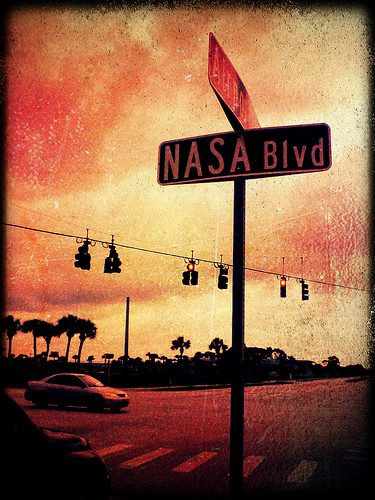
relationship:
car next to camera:
[21, 354, 137, 414] [26, 411, 102, 461]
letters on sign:
[160, 144, 180, 180] [158, 122, 333, 185]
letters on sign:
[183, 138, 202, 176] [158, 122, 333, 185]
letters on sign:
[205, 136, 223, 174] [158, 122, 333, 185]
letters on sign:
[228, 135, 252, 173] [158, 122, 333, 185]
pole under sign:
[226, 174, 245, 498] [152, 33, 337, 187]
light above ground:
[278, 276, 287, 296] [6, 378, 371, 497]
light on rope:
[272, 264, 289, 309] [289, 262, 358, 304]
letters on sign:
[164, 144, 180, 180] [158, 122, 333, 185]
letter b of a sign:
[261, 138, 278, 171] [157, 118, 335, 179]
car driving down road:
[24, 373, 130, 414] [13, 378, 371, 497]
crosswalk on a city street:
[64, 432, 374, 493] [29, 360, 374, 487]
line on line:
[3, 222, 231, 266] [70, 237, 90, 270]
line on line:
[3, 222, 231, 266] [4, 222, 231, 265]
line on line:
[3, 222, 231, 266] [104, 216, 237, 281]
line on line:
[244, 266, 370, 296] [240, 254, 364, 301]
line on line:
[244, 266, 370, 296] [295, 272, 320, 313]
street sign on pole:
[153, 120, 333, 188] [226, 174, 245, 498]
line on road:
[94, 442, 131, 458] [13, 378, 371, 497]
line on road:
[120, 444, 171, 470] [13, 378, 371, 497]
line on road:
[173, 450, 216, 473] [13, 378, 371, 497]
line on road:
[228, 454, 264, 476] [13, 378, 371, 497]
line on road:
[288, 457, 318, 486] [13, 378, 371, 497]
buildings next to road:
[272, 332, 334, 383] [11, 368, 358, 487]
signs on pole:
[147, 16, 342, 191] [213, 171, 259, 496]